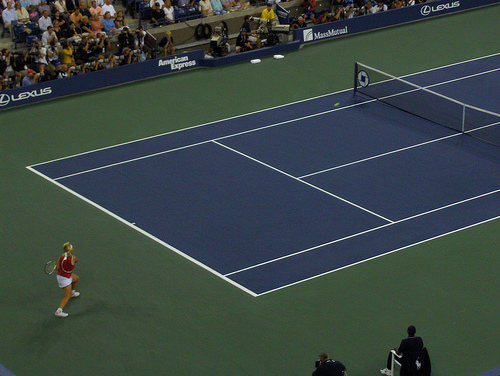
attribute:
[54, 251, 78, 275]
shirt — red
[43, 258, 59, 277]
racket — tennis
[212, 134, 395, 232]
line — white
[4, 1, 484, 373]
trim — green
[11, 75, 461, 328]
match — tennis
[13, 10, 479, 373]
court — tennis, large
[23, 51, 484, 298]
court — tennis, blue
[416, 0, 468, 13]
logo — Lexus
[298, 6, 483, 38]
wall — short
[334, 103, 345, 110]
ball — tennis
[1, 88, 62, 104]
word — Lexus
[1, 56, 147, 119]
wall — short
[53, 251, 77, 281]
top — red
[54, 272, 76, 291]
skirt — white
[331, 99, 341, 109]
ball — tennis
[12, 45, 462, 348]
court — green, blue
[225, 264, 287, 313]
lines — White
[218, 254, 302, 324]
lines — White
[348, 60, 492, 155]
net — blue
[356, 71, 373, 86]
logo — White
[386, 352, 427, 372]
white stand — white 